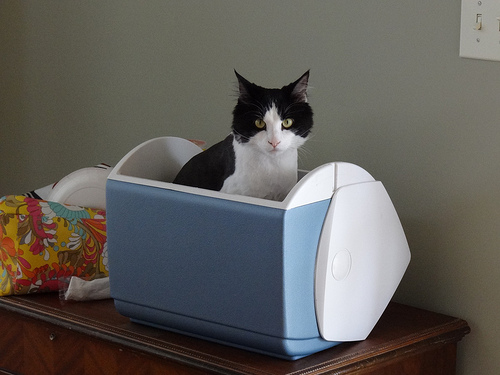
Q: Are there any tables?
A: Yes, there is a table.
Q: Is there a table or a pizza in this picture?
A: Yes, there is a table.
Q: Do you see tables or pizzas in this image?
A: Yes, there is a table.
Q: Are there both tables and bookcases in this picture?
A: No, there is a table but no bookcases.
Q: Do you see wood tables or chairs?
A: Yes, there is a wood table.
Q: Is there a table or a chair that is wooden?
A: Yes, the table is wooden.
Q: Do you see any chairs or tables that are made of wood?
A: Yes, the table is made of wood.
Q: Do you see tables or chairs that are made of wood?
A: Yes, the table is made of wood.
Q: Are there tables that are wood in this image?
A: Yes, there is a wood table.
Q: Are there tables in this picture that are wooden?
A: Yes, there is a table that is wooden.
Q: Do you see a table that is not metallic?
A: Yes, there is a wooden table.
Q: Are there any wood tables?
A: Yes, there is a table that is made of wood.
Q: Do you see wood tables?
A: Yes, there is a table that is made of wood.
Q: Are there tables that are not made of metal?
A: Yes, there is a table that is made of wood.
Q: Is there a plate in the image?
A: No, there are no plates.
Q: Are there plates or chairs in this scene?
A: No, there are no plates or chairs.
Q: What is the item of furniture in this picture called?
A: The piece of furniture is a table.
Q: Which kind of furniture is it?
A: The piece of furniture is a table.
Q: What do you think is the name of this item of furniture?
A: This is a table.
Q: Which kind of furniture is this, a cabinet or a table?
A: This is a table.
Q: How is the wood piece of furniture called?
A: The piece of furniture is a table.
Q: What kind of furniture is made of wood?
A: The furniture is a table.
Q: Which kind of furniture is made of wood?
A: The furniture is a table.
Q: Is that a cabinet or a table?
A: That is a table.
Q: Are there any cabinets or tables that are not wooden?
A: No, there is a table but it is wooden.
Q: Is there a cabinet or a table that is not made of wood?
A: No, there is a table but it is made of wood.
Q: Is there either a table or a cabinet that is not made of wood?
A: No, there is a table but it is made of wood.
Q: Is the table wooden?
A: Yes, the table is wooden.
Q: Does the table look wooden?
A: Yes, the table is wooden.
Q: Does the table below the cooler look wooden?
A: Yes, the table is wooden.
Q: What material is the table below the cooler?
A: The table is made of wood.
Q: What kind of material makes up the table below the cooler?
A: The table is made of wood.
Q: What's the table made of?
A: The table is made of wood.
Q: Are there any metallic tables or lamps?
A: No, there is a table but it is wooden.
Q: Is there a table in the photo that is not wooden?
A: No, there is a table but it is wooden.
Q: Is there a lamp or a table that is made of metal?
A: No, there is a table but it is made of wood.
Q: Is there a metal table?
A: No, there is a table but it is made of wood.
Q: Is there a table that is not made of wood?
A: No, there is a table but it is made of wood.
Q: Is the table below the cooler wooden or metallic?
A: The table is wooden.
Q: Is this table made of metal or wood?
A: The table is made of wood.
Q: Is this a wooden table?
A: Yes, this is a wooden table.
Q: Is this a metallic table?
A: No, this is a wooden table.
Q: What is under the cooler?
A: The table is under the cooler.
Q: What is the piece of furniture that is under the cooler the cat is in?
A: The piece of furniture is a table.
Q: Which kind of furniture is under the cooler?
A: The piece of furniture is a table.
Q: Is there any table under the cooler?
A: Yes, there is a table under the cooler.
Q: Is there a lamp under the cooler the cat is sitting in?
A: No, there is a table under the cooler.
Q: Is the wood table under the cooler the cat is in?
A: Yes, the table is under the cooler.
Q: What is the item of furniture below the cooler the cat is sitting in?
A: The piece of furniture is a table.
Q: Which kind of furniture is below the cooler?
A: The piece of furniture is a table.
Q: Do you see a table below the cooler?
A: Yes, there is a table below the cooler.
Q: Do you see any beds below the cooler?
A: No, there is a table below the cooler.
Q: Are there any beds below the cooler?
A: No, there is a table below the cooler.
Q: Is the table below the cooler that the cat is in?
A: Yes, the table is below the cooler.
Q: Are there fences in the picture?
A: No, there are no fences.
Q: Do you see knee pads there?
A: No, there are no knee pads.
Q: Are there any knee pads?
A: No, there are no knee pads.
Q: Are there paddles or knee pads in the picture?
A: No, there are no knee pads or paddles.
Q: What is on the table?
A: The cooler is on the table.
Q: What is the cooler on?
A: The cooler is on the table.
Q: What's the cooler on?
A: The cooler is on the table.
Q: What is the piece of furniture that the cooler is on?
A: The piece of furniture is a table.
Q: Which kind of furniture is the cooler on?
A: The cooler is on the table.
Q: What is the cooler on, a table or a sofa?
A: The cooler is on a table.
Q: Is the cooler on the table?
A: Yes, the cooler is on the table.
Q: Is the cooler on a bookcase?
A: No, the cooler is on the table.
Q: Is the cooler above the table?
A: Yes, the cooler is above the table.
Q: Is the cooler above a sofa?
A: No, the cooler is above the table.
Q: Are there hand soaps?
A: No, there are no hand soaps.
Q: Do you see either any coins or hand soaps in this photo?
A: No, there are no hand soaps or coins.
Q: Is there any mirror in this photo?
A: No, there are no mirrors.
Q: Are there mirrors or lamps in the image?
A: No, there are no mirrors or lamps.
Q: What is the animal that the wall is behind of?
A: The animal is a cat.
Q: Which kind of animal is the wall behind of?
A: The wall is behind the cat.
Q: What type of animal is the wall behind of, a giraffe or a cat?
A: The wall is behind a cat.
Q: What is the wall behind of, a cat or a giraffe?
A: The wall is behind a cat.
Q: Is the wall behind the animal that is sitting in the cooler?
A: Yes, the wall is behind the cat.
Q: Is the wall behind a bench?
A: No, the wall is behind the cat.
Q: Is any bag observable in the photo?
A: Yes, there is a bag.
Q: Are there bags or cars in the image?
A: Yes, there is a bag.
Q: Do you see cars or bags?
A: Yes, there is a bag.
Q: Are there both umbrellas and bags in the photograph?
A: No, there is a bag but no umbrellas.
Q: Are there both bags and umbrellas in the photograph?
A: No, there is a bag but no umbrellas.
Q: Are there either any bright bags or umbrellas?
A: Yes, there is a bright bag.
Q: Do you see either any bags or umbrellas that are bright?
A: Yes, the bag is bright.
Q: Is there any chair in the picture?
A: No, there are no chairs.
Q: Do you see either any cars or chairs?
A: No, there are no chairs or cars.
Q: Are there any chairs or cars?
A: No, there are no chairs or cars.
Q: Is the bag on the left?
A: Yes, the bag is on the left of the image.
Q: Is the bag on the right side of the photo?
A: No, the bag is on the left of the image.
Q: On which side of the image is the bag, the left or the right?
A: The bag is on the left of the image.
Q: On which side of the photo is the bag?
A: The bag is on the left of the image.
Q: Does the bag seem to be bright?
A: Yes, the bag is bright.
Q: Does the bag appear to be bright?
A: Yes, the bag is bright.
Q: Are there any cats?
A: Yes, there is a cat.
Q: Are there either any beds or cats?
A: Yes, there is a cat.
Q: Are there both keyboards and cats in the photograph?
A: No, there is a cat but no keyboards.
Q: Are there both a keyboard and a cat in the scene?
A: No, there is a cat but no keyboards.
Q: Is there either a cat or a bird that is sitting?
A: Yes, the cat is sitting.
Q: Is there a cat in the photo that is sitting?
A: Yes, there is a cat that is sitting.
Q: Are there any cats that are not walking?
A: Yes, there is a cat that is sitting.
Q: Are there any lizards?
A: No, there are no lizards.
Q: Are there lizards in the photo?
A: No, there are no lizards.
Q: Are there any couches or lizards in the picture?
A: No, there are no lizards or couches.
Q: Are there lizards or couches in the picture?
A: No, there are no lizards or couches.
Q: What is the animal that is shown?
A: The animal is a cat.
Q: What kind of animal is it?
A: The animal is a cat.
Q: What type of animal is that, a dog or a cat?
A: This is a cat.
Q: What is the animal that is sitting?
A: The animal is a cat.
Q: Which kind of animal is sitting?
A: The animal is a cat.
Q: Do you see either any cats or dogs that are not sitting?
A: No, there is a cat but it is sitting.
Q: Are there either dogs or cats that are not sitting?
A: No, there is a cat but it is sitting.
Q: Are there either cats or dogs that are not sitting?
A: No, there is a cat but it is sitting.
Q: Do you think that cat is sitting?
A: Yes, the cat is sitting.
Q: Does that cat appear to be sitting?
A: Yes, the cat is sitting.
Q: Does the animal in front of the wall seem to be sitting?
A: Yes, the cat is sitting.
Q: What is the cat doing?
A: The cat is sitting.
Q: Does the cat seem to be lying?
A: No, the cat is sitting.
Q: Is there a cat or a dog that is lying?
A: No, there is a cat but it is sitting.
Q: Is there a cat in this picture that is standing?
A: No, there is a cat but it is sitting.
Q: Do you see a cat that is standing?
A: No, there is a cat but it is sitting.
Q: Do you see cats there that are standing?
A: No, there is a cat but it is sitting.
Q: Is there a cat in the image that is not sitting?
A: No, there is a cat but it is sitting.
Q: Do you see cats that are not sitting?
A: No, there is a cat but it is sitting.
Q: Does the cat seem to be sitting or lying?
A: The cat is sitting.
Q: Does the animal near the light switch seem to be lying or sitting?
A: The cat is sitting.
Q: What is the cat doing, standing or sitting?
A: The cat is sitting.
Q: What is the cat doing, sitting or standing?
A: The cat is sitting.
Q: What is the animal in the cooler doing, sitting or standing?
A: The cat is sitting.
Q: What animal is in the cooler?
A: The animal is a cat.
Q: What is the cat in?
A: The cat is in the cooler.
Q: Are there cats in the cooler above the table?
A: Yes, there is a cat in the cooler.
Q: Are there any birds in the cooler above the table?
A: No, there is a cat in the cooler.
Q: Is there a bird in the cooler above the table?
A: No, there is a cat in the cooler.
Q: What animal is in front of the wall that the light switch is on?
A: The cat is in front of the wall.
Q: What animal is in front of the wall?
A: The cat is in front of the wall.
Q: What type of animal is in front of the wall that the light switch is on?
A: The animal is a cat.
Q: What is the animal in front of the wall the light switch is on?
A: The animal is a cat.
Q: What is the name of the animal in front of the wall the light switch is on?
A: The animal is a cat.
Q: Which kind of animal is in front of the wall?
A: The animal is a cat.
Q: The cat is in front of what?
A: The cat is in front of the wall.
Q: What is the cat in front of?
A: The cat is in front of the wall.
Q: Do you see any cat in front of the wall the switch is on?
A: Yes, there is a cat in front of the wall.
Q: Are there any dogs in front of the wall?
A: No, there is a cat in front of the wall.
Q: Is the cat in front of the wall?
A: Yes, the cat is in front of the wall.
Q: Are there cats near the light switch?
A: Yes, there is a cat near the light switch.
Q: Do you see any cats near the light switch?
A: Yes, there is a cat near the light switch.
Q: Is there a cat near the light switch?
A: Yes, there is a cat near the light switch.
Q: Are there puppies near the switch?
A: No, there is a cat near the switch.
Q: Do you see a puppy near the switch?
A: No, there is a cat near the switch.